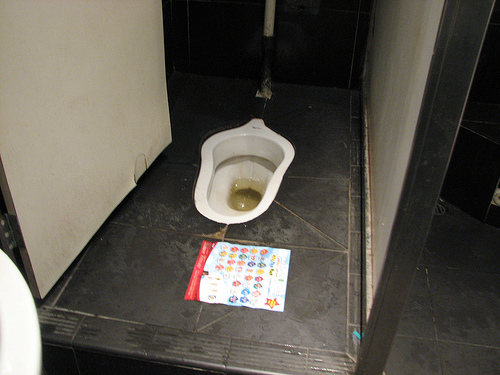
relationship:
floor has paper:
[31, 74, 362, 374] [182, 240, 293, 313]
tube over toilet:
[259, 4, 275, 93] [195, 118, 294, 224]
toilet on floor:
[195, 118, 294, 224] [31, 74, 362, 374]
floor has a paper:
[31, 74, 362, 374] [182, 238, 293, 313]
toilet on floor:
[188, 118, 297, 227] [31, 74, 362, 374]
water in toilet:
[228, 178, 266, 210] [188, 118, 297, 227]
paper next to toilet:
[182, 240, 293, 313] [188, 118, 297, 227]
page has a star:
[181, 241, 216, 300] [267, 296, 282, 309]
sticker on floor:
[183, 238, 291, 314] [31, 74, 362, 374]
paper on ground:
[182, 240, 293, 313] [35, 72, 365, 374]